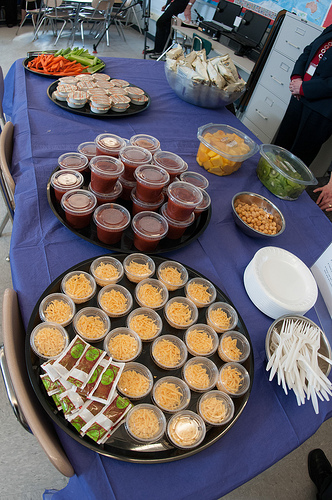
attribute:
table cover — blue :
[1, 50, 330, 497]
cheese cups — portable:
[27, 252, 251, 452]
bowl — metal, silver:
[265, 312, 331, 383]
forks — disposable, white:
[264, 317, 331, 416]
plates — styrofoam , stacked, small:
[243, 245, 318, 320]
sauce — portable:
[51, 130, 211, 255]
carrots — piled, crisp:
[22, 53, 88, 74]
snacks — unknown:
[164, 43, 248, 107]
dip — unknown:
[51, 72, 147, 116]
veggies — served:
[26, 47, 104, 77]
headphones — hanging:
[214, 1, 256, 25]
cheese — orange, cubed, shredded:
[130, 314, 157, 337]